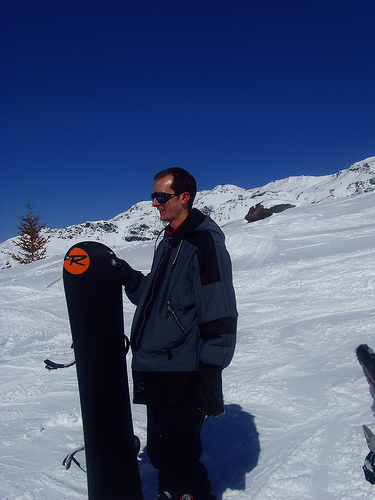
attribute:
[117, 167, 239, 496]
man — real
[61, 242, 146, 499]
board — black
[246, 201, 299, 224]
rock — covered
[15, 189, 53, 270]
tree — brown, far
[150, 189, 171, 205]
sunglasses — real, blue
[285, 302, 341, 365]
snow — tracked, tracks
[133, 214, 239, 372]
coat — blue, gray, big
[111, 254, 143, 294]
glove — black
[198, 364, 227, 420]
glove — black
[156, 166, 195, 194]
hair — dark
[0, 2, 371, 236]
sky — blue